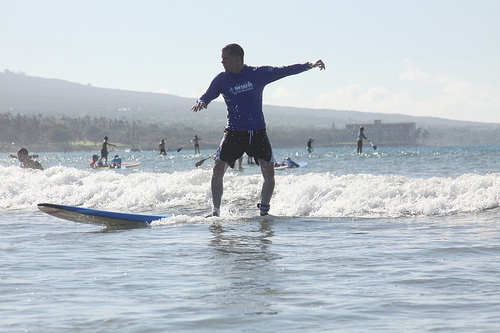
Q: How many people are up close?
A: One.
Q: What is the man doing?
A: Surfing.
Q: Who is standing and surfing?
A: A man.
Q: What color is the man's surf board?
A: Blue.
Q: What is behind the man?
A: A wave.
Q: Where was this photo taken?
A: Outside at the beach.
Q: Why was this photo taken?
A: To show the man surfing.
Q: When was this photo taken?
A: During the day.